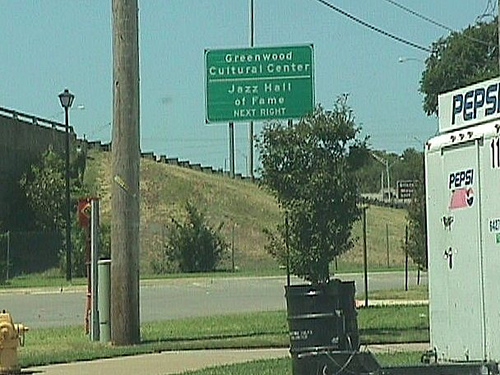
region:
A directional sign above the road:
[201, 42, 316, 122]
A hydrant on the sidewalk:
[0, 311, 27, 371]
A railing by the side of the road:
[1, 105, 74, 134]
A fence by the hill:
[1, 223, 411, 278]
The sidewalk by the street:
[4, 339, 429, 374]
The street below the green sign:
[0, 269, 425, 334]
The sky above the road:
[1, 0, 498, 177]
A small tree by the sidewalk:
[255, 92, 369, 282]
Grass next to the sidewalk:
[0, 284, 428, 374]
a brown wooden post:
[96, 19, 162, 357]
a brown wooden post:
[82, 28, 166, 370]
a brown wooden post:
[95, 25, 160, 369]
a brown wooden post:
[94, 35, 171, 370]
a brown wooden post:
[99, 50, 159, 332]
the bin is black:
[274, 271, 370, 369]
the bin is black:
[278, 274, 360, 374]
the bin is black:
[274, 272, 348, 372]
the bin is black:
[272, 270, 359, 374]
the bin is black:
[270, 253, 379, 370]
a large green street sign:
[205, 45, 313, 121]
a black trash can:
[285, 280, 358, 374]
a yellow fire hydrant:
[0, 313, 26, 370]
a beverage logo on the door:
[449, 169, 474, 208]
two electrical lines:
[316, 0, 469, 52]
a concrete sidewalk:
[22, 341, 429, 373]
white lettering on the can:
[288, 330, 310, 340]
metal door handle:
[442, 216, 454, 228]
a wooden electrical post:
[112, 0, 140, 344]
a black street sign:
[397, 180, 412, 199]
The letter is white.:
[205, 60, 216, 76]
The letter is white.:
[265, 60, 275, 75]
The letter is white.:
[220, 48, 235, 67]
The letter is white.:
[225, 77, 239, 97]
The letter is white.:
[260, 76, 274, 96]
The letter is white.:
[231, 103, 241, 120]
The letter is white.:
[257, 104, 267, 117]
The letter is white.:
[269, 78, 283, 94]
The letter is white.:
[278, 78, 288, 95]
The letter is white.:
[284, 77, 294, 97]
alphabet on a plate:
[217, 53, 235, 64]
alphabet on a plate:
[205, 66, 222, 77]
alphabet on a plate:
[225, 99, 242, 117]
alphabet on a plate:
[277, 101, 292, 123]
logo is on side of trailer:
[444, 165, 476, 207]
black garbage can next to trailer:
[285, 275, 358, 373]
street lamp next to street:
[54, 83, 82, 285]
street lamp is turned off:
[54, 86, 82, 284]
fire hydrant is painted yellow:
[1, 308, 29, 374]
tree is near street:
[248, 94, 374, 283]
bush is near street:
[154, 200, 234, 275]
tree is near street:
[22, 133, 96, 281]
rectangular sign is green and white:
[202, 40, 319, 125]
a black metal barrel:
[285, 271, 375, 373]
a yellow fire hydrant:
[0, 301, 29, 373]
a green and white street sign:
[197, 37, 320, 132]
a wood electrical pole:
[101, 0, 141, 342]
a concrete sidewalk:
[53, 346, 281, 373]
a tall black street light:
[55, 77, 77, 280]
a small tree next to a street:
[260, 77, 372, 297]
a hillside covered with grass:
[156, 152, 277, 262]